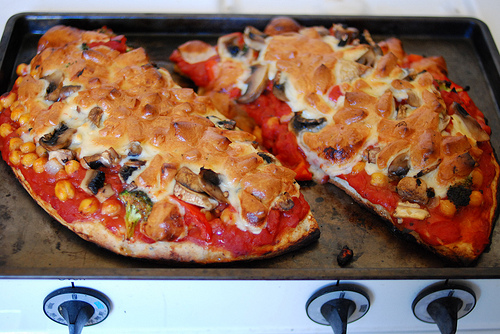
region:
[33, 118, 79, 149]
mushroom on a pizza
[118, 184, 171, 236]
broccoli on a pizza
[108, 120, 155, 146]
brown cheese on a pizza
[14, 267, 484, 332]
temperature control knobs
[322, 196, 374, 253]
a metal pan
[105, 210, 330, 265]
crust on a pizza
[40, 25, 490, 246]
a pizza sliced in half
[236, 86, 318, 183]
tomato pizza sauce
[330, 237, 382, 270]
piece of burnt food on a pan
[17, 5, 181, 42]
side of a metal baking pan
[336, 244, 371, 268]
black and red button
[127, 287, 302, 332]
light green color on surface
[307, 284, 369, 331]
black and gray knob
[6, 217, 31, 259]
little brown spot on surface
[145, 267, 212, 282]
edge of light brown surface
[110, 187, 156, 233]
juicy piece of broccolli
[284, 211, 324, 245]
brown crust of dough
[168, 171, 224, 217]
small piece of chicken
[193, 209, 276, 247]
red sauce on dough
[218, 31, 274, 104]
juicy pieces of mushroom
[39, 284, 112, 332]
a black dial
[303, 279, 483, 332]
a pair of black dials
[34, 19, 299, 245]
melted cheese on pizza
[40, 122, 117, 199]
mushrooms on a pizza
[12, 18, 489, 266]
a delicious pizza sliced in half on a baking sheet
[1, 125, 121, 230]
yellow corn on a pizza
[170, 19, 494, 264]
half of a pizza with a crispy crust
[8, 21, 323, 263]
half of a pizza with red tomato sauce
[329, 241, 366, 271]
a dead fly on a baking sheet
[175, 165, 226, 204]
Mushroom on pizza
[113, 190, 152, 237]
Broccoli on pizza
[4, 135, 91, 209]
Yellow corn on pizza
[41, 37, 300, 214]
Melted cheese on pizza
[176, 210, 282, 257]
Pizza sauce on pizza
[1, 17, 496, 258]
Two pizza halves on cookie sheet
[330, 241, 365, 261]
Burnt crumb of pizza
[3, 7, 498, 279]
Cookie sheet with two pizza halves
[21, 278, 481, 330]
Dials on the stove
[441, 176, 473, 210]
Burnt broccoli on pizza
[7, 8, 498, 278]
The pizzas are on a tray.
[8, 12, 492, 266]
There are two pizzas.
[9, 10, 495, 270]
The pizzas are cooked.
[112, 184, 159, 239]
There is broccoli on the pizza.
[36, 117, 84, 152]
There are mushrooms on the pizza.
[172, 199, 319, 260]
There is pizza sauce on the pizza.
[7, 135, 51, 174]
There are chickpeas on the pizza.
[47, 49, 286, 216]
There is cheese on the pizza.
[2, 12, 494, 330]
The tray is on a stove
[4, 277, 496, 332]
There are three dials for the stove.